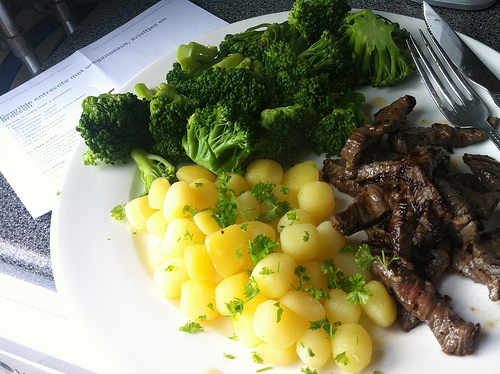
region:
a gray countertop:
[0, 0, 499, 293]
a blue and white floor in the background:
[0, 0, 104, 96]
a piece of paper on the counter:
[0, 0, 230, 218]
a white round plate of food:
[49, 8, 499, 372]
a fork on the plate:
[405, 27, 499, 150]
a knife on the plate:
[421, 0, 498, 108]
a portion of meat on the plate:
[320, 93, 498, 356]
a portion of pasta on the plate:
[125, 158, 397, 373]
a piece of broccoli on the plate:
[182, 101, 254, 177]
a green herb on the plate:
[245, 232, 279, 263]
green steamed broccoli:
[79, 5, 405, 175]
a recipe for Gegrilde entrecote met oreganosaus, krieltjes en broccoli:
[0, 11, 183, 151]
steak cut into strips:
[332, 95, 497, 351]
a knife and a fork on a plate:
[405, 8, 498, 159]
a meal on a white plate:
[44, 7, 499, 369]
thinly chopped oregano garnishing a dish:
[172, 172, 384, 330]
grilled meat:
[323, 101, 498, 318]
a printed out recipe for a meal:
[2, 12, 206, 210]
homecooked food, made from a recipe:
[5, 5, 492, 366]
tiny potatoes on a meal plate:
[107, 153, 422, 372]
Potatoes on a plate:
[189, 250, 229, 295]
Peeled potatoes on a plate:
[201, 255, 229, 290]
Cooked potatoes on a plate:
[190, 255, 228, 290]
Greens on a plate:
[195, 85, 270, 120]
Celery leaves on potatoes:
[251, 240, 261, 250]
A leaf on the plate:
[186, 325, 193, 330]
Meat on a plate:
[401, 285, 426, 305]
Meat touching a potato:
[332, 216, 347, 222]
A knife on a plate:
[435, 24, 445, 36]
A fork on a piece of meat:
[471, 113, 486, 124]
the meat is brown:
[346, 111, 488, 348]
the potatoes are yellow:
[129, 140, 391, 372]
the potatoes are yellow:
[190, 199, 365, 349]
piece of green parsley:
[242, 273, 261, 300]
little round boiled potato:
[330, 320, 374, 371]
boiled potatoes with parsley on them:
[118, 155, 393, 372]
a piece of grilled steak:
[368, 247, 483, 357]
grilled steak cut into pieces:
[318, 87, 498, 352]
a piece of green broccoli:
[177, 100, 252, 178]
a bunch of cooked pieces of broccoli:
[75, 0, 415, 181]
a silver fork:
[403, 25, 498, 155]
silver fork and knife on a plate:
[398, 0, 498, 165]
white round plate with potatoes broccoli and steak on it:
[43, 3, 498, 370]